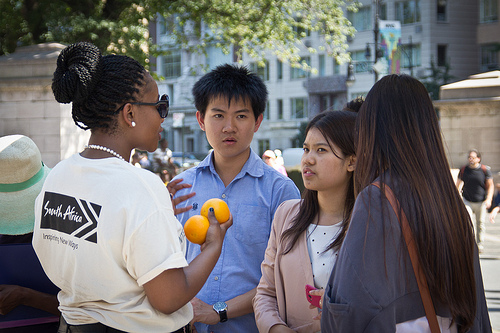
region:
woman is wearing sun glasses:
[105, 86, 181, 116]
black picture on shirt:
[30, 181, 117, 251]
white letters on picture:
[32, 183, 83, 233]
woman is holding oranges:
[172, 177, 230, 248]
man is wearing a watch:
[205, 283, 240, 329]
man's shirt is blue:
[170, 160, 291, 306]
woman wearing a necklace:
[67, 122, 118, 162]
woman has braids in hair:
[28, 35, 144, 140]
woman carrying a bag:
[370, 181, 467, 326]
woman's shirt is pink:
[251, 191, 318, 331]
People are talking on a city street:
[30, 20, 485, 321]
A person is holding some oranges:
[36, 10, 463, 316]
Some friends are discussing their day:
[36, 12, 491, 313]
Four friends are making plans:
[32, 35, 475, 316]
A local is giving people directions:
[20, 15, 485, 315]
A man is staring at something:
[20, 20, 475, 315]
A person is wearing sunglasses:
[40, 27, 180, 157]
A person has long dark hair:
[353, 60, 474, 311]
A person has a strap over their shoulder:
[348, 62, 474, 328]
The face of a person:
[211, 104, 248, 147]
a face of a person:
[205, 99, 253, 151]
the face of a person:
[299, 136, 330, 191]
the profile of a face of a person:
[148, 85, 167, 153]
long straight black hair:
[383, 74, 484, 331]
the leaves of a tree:
[228, 5, 287, 35]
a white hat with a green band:
[2, 133, 42, 236]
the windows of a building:
[271, 73, 307, 125]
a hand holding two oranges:
[186, 197, 241, 250]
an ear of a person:
[120, 100, 142, 133]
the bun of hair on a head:
[51, 39, 101, 107]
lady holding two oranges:
[31, 16, 233, 328]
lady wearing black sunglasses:
[26, 28, 222, 331]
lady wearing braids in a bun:
[16, 40, 208, 327]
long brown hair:
[361, 70, 498, 318]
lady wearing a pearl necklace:
[31, 38, 236, 330]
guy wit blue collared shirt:
[168, 40, 308, 319]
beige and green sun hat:
[0, 118, 61, 247]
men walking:
[459, 141, 496, 237]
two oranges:
[182, 190, 243, 258]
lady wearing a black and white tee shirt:
[24, 23, 234, 330]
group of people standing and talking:
[21, 29, 488, 331]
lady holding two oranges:
[165, 180, 250, 292]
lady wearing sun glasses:
[106, 66, 189, 138]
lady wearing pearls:
[68, 121, 190, 207]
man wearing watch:
[203, 287, 255, 322]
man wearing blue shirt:
[176, 125, 302, 320]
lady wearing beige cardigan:
[245, 173, 337, 331]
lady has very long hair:
[343, 56, 498, 327]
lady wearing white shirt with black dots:
[271, 192, 351, 320]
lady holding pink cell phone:
[278, 275, 355, 324]